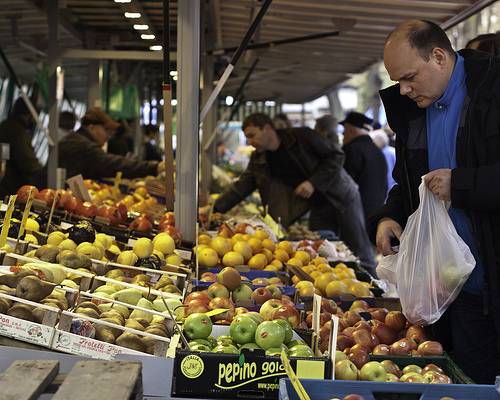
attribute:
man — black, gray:
[366, 17, 499, 382]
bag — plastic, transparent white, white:
[376, 176, 477, 328]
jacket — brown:
[212, 126, 360, 227]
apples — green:
[183, 309, 313, 357]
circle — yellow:
[179, 355, 204, 378]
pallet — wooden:
[1, 358, 145, 399]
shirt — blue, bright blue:
[423, 50, 485, 294]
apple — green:
[254, 321, 287, 350]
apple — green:
[183, 312, 213, 341]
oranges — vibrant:
[196, 229, 374, 298]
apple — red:
[385, 309, 408, 334]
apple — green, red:
[217, 266, 242, 291]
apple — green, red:
[208, 285, 230, 299]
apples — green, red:
[185, 265, 302, 330]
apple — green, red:
[207, 297, 234, 322]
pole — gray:
[174, 1, 200, 245]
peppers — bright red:
[15, 185, 176, 232]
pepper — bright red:
[128, 218, 153, 234]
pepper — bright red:
[74, 200, 95, 218]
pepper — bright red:
[99, 205, 123, 226]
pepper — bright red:
[36, 188, 61, 211]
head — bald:
[383, 19, 454, 108]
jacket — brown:
[38, 124, 160, 187]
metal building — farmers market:
[1, 0, 499, 399]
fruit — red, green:
[358, 360, 388, 381]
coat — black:
[365, 49, 497, 318]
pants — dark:
[428, 292, 499, 383]